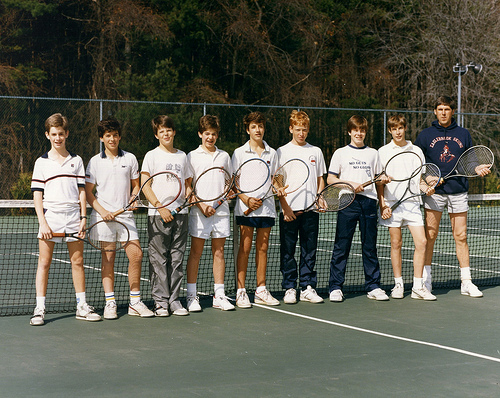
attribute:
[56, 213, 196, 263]
racket — held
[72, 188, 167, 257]
racket — held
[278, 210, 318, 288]
jeans — blue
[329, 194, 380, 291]
jeans — blue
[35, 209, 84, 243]
shorts — white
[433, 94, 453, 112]
hair — brown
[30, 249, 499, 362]
line — white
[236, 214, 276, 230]
shorts — black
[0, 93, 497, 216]
fence — chain link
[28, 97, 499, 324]
tennis players — posing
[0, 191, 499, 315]
tennis net — black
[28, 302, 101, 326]
shoes — white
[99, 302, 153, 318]
shoes — white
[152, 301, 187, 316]
shoes — white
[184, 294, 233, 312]
shoes — white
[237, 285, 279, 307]
shoes — white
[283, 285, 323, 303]
shoes — white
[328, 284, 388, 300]
shoes — white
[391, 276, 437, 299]
shoes — white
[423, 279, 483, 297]
shoes — white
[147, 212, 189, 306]
pants — gray, long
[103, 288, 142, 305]
socks — white, striped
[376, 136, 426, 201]
shirt — white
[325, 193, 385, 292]
pants — blue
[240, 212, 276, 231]
shorts — blue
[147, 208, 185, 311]
pants — gray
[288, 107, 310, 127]
hair — red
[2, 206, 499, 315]
strings — black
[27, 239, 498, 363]
lines — white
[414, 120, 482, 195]
sweatshirt — hooded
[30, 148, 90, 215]
shirt — white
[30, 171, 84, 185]
stripe — red, horizontal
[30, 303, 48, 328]
sneaker — white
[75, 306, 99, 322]
sneaker — white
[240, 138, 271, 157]
collar — open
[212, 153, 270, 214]
racket — TENNIS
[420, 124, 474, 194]
sweatshirt — HOODED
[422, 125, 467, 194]
sweatshirt — BLUE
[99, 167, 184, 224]
racket — tennis